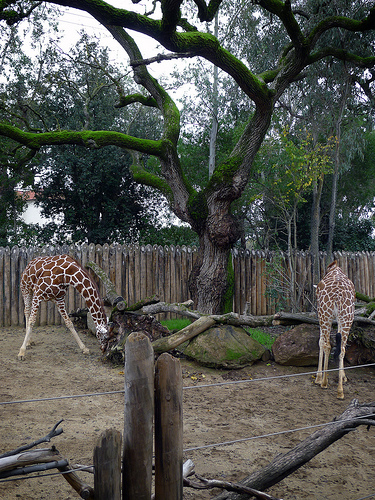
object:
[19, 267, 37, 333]
back legs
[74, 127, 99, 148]
moss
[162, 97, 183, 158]
branch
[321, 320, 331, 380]
front leg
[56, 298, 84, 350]
leg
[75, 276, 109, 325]
neck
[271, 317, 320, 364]
rocks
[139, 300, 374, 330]
branches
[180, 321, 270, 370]
rocks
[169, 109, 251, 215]
green trees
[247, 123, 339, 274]
green trees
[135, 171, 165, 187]
moss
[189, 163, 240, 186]
moss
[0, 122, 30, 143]
moss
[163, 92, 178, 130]
moss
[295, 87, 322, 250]
tree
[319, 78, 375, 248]
tree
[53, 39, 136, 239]
tree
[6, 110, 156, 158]
branch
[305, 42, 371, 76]
branch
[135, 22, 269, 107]
branch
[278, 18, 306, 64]
branch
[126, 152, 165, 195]
branch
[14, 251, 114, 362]
giraffe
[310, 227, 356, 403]
giraffe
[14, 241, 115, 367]
giraffe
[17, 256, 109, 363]
giraffes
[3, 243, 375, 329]
fence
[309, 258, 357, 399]
giraffe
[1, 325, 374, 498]
fence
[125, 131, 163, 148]
moss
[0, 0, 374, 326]
tree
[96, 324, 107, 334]
ears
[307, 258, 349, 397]
giraffe